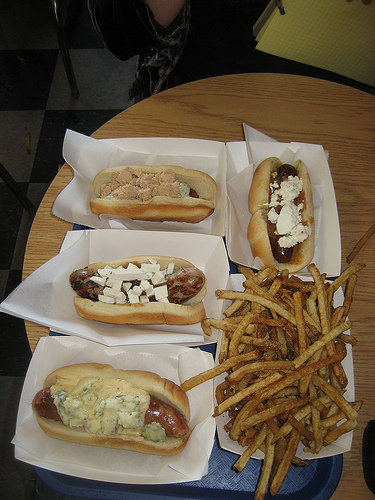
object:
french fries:
[178, 350, 257, 394]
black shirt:
[87, 3, 194, 100]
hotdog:
[84, 163, 220, 226]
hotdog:
[245, 153, 317, 275]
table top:
[20, 71, 374, 498]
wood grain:
[99, 285, 128, 306]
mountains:
[215, 276, 348, 452]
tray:
[0, 228, 233, 351]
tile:
[0, 111, 45, 186]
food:
[113, 165, 134, 187]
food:
[275, 202, 298, 237]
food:
[153, 283, 170, 303]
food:
[49, 374, 152, 437]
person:
[87, 0, 258, 107]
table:
[20, 70, 373, 499]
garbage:
[22, 130, 35, 161]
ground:
[0, 0, 144, 498]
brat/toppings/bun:
[68, 261, 206, 304]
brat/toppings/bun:
[30, 383, 190, 440]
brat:
[88, 162, 220, 225]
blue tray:
[27, 221, 344, 499]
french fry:
[178, 348, 260, 393]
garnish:
[287, 186, 297, 198]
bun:
[30, 359, 193, 457]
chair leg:
[53, 4, 82, 102]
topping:
[98, 164, 189, 201]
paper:
[9, 334, 217, 484]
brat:
[187, 186, 198, 201]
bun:
[88, 164, 217, 222]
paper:
[71, 137, 227, 233]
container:
[224, 137, 343, 282]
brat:
[264, 164, 304, 266]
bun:
[244, 153, 316, 276]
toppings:
[48, 373, 151, 421]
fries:
[230, 422, 269, 472]